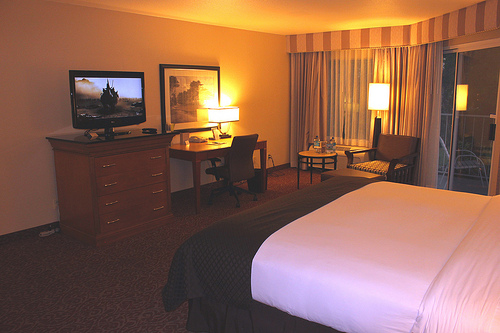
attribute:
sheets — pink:
[246, 181, 498, 331]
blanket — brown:
[168, 174, 362, 324]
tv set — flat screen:
[64, 61, 147, 135]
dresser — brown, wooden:
[50, 137, 180, 264]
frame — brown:
[152, 59, 233, 135]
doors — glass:
[426, 48, 498, 180]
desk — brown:
[173, 132, 269, 215]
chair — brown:
[210, 134, 262, 215]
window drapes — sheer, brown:
[284, 44, 447, 180]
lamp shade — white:
[366, 79, 389, 115]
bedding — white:
[248, 181, 498, 330]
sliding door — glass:
[426, 46, 498, 189]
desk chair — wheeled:
[206, 126, 256, 207]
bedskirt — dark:
[155, 165, 388, 326]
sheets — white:
[243, 163, 496, 327]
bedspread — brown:
[147, 166, 396, 330]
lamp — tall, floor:
[352, 65, 402, 161]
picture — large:
[152, 54, 232, 147]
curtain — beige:
[276, 36, 456, 185]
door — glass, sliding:
[421, 35, 494, 187]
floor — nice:
[0, 153, 342, 330]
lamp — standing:
[352, 71, 400, 167]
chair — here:
[198, 123, 270, 211]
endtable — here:
[286, 129, 344, 191]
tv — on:
[58, 61, 158, 140]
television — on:
[63, 60, 155, 140]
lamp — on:
[355, 76, 398, 136]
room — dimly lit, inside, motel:
[11, 0, 498, 330]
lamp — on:
[199, 94, 241, 139]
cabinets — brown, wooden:
[43, 119, 184, 250]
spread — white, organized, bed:
[239, 171, 463, 326]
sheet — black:
[159, 173, 373, 313]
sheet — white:
[252, 180, 498, 331]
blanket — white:
[250, 179, 499, 331]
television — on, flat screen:
[66, 64, 148, 138]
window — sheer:
[285, 3, 499, 193]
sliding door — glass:
[438, 38, 498, 192]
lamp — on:
[364, 79, 393, 150]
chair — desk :
[218, 121, 274, 209]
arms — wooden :
[204, 153, 228, 199]